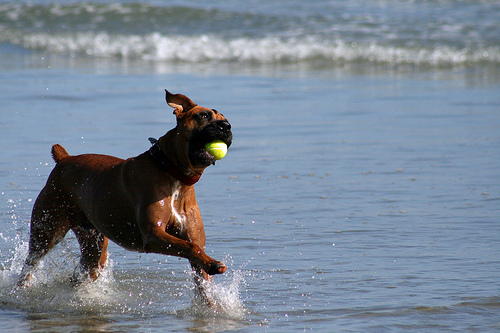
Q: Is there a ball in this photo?
A: Yes, there is a ball.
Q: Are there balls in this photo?
A: Yes, there is a ball.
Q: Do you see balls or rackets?
A: Yes, there is a ball.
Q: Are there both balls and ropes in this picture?
A: No, there is a ball but no ropes.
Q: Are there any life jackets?
A: No, there are no life jackets.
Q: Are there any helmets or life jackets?
A: No, there are no life jackets or helmets.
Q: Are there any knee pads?
A: No, there are no knee pads.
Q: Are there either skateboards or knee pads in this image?
A: No, there are no knee pads or skateboards.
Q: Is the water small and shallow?
A: Yes, the water is small and shallow.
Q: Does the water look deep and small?
A: No, the water is small but shallow.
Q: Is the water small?
A: Yes, the water is small.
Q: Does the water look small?
A: Yes, the water is small.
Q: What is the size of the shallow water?
A: The water is small.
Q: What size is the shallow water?
A: The water is small.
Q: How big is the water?
A: The water is small.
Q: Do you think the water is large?
A: No, the water is small.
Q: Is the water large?
A: No, the water is small.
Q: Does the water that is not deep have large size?
A: No, the water is small.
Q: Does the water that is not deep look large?
A: No, the water is small.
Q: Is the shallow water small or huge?
A: The water is small.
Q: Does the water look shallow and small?
A: Yes, the water is shallow and small.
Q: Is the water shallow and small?
A: Yes, the water is shallow and small.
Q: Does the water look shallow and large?
A: No, the water is shallow but small.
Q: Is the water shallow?
A: Yes, the water is shallow.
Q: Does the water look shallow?
A: Yes, the water is shallow.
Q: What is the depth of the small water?
A: The water is shallow.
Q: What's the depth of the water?
A: The water is shallow.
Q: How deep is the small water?
A: The water is shallow.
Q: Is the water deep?
A: No, the water is shallow.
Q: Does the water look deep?
A: No, the water is shallow.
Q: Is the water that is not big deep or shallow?
A: The water is shallow.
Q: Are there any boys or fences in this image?
A: No, there are no fences or boys.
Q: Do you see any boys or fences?
A: No, there are no fences or boys.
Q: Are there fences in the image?
A: No, there are no fences.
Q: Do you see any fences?
A: No, there are no fences.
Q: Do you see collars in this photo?
A: Yes, there is a collar.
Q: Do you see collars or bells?
A: Yes, there is a collar.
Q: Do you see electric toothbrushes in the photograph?
A: No, there are no electric toothbrushes.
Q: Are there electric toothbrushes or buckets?
A: No, there are no electric toothbrushes or buckets.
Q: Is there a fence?
A: No, there are no fences.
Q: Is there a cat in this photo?
A: No, there are no cats.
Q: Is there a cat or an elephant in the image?
A: No, there are no cats or elephants.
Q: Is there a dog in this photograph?
A: Yes, there is a dog.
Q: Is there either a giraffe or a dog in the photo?
A: Yes, there is a dog.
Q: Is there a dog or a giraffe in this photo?
A: Yes, there is a dog.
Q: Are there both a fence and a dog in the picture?
A: No, there is a dog but no fences.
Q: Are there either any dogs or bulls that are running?
A: Yes, the dog is running.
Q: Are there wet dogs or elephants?
A: Yes, there is a wet dog.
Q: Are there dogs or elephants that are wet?
A: Yes, the dog is wet.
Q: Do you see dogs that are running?
A: Yes, there is a dog that is running.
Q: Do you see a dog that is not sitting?
A: Yes, there is a dog that is running .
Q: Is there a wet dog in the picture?
A: Yes, there is a wet dog.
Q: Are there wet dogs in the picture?
A: Yes, there is a wet dog.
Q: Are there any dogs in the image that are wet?
A: Yes, there is a dog that is wet.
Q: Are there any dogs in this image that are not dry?
A: Yes, there is a wet dog.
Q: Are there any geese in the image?
A: No, there are no geese.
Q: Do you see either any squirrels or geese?
A: No, there are no geese or squirrels.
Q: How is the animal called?
A: The animal is a dog.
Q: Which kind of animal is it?
A: The animal is a dog.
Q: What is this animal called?
A: That is a dog.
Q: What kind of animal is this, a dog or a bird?
A: That is a dog.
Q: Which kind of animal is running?
A: The animal is a dog.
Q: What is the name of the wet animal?
A: The animal is a dog.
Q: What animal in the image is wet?
A: The animal is a dog.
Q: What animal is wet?
A: The animal is a dog.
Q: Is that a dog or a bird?
A: That is a dog.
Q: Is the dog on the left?
A: Yes, the dog is on the left of the image.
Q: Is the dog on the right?
A: No, the dog is on the left of the image.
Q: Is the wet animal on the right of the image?
A: No, the dog is on the left of the image.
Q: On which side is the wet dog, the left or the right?
A: The dog is on the left of the image.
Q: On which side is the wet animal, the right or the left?
A: The dog is on the left of the image.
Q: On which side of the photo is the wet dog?
A: The dog is on the left of the image.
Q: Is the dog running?
A: Yes, the dog is running.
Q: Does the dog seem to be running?
A: Yes, the dog is running.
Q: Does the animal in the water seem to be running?
A: Yes, the dog is running.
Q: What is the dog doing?
A: The dog is running.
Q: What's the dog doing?
A: The dog is running.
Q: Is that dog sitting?
A: No, the dog is running.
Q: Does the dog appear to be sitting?
A: No, the dog is running.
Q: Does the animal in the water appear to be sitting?
A: No, the dog is running.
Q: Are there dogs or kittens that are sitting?
A: No, there is a dog but it is running.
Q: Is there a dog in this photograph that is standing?
A: No, there is a dog but it is running.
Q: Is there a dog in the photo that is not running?
A: No, there is a dog but it is running.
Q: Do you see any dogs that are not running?
A: No, there is a dog but it is running.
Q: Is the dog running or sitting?
A: The dog is running.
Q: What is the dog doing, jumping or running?
A: The dog is running.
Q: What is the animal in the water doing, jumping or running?
A: The dog is running.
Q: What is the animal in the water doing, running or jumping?
A: The dog is running.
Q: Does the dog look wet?
A: Yes, the dog is wet.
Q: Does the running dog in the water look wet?
A: Yes, the dog is wet.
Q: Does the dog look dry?
A: No, the dog is wet.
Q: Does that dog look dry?
A: No, the dog is wet.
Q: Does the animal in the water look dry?
A: No, the dog is wet.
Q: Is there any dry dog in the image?
A: No, there is a dog but it is wet.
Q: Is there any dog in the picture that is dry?
A: No, there is a dog but it is wet.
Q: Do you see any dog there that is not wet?
A: No, there is a dog but it is wet.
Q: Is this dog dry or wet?
A: The dog is wet.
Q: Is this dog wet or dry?
A: The dog is wet.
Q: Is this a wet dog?
A: Yes, this is a wet dog.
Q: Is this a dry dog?
A: No, this is a wet dog.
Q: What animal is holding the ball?
A: The dog is holding the ball.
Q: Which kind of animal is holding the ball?
A: The animal is a dog.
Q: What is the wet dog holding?
A: The dog is holding the ball.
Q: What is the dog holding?
A: The dog is holding the ball.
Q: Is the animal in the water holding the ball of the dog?
A: Yes, the dog is holding the ball.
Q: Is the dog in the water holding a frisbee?
A: No, the dog is holding the ball.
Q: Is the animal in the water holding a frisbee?
A: No, the dog is holding the ball.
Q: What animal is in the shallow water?
A: The dog is in the water.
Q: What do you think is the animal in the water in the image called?
A: The animal is a dog.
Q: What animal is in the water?
A: The animal is a dog.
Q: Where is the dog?
A: The dog is in the water.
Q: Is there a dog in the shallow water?
A: Yes, there is a dog in the water.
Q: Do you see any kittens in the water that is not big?
A: No, there is a dog in the water.